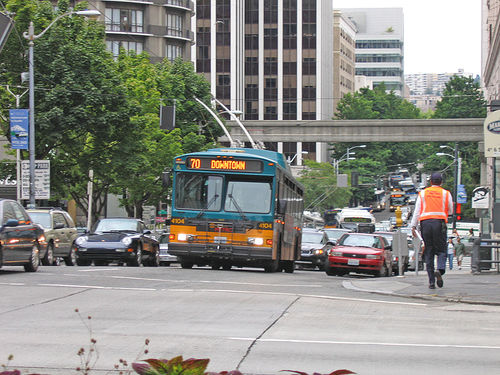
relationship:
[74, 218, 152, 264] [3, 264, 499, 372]
cars on road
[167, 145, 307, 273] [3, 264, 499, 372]
green and yellow bus on road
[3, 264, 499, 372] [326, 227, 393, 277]
road has a vehicle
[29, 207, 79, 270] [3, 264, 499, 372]
vehicle on road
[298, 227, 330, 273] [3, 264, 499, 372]
vehicle on road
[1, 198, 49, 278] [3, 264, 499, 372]
vehicle on road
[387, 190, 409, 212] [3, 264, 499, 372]
vehicle on road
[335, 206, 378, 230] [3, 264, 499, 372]
vehicle on road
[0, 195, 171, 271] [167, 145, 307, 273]
cars and green and yellow bus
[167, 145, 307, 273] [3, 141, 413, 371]
green and yellow bus number going downtown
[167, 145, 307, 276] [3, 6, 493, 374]
green and yellow bus going downtown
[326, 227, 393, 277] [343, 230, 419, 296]
red car parked next to curb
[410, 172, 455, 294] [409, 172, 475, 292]
man wearing orange reflector coat people walking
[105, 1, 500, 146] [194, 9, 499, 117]
highrise buildings in background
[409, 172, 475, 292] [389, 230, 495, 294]
people walking on sidewalk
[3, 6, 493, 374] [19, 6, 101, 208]
trees, cars, signs and a light post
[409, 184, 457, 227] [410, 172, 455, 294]
orange vest on a person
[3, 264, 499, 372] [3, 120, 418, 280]
paved road with cars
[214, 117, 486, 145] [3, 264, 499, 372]
overpass over road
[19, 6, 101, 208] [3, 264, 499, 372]
lamp post on a road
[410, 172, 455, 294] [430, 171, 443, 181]
person wearing a hat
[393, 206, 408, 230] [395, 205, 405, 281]
yellow parking meter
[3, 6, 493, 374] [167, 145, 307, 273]
downtown displayed on a green and yellow bus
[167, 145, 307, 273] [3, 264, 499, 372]
green and yellow bus driving down street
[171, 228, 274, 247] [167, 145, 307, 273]
head lights on front of green and yellow bus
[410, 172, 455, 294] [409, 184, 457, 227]
person walking in safety vest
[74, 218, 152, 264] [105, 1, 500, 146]
cars driving past buildings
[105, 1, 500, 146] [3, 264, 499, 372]
building lining city street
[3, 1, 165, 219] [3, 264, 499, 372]
green trees lining city street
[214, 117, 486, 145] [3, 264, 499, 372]
bridge over city street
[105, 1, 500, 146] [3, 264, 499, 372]
buildings near city street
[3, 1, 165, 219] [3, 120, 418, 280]
leafy trees near city traffic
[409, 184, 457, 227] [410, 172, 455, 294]
orange vest that person is wearing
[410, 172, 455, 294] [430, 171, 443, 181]
person wearing hat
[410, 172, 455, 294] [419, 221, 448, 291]
person with dark pants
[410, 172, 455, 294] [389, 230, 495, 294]
person on sidewalk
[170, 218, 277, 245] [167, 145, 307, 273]
yellow writing on green and yellow bus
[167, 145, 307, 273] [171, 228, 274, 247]
green and yellow bus has headlights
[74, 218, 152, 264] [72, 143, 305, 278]
cars that small near bus